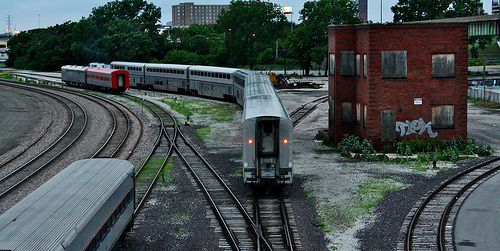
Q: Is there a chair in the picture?
A: No, there are no chairs.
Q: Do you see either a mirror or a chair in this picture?
A: No, there are no chairs or mirrors.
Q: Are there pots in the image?
A: No, there are no pots.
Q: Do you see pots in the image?
A: No, there are no pots.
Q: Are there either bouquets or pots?
A: No, there are no pots or bouquets.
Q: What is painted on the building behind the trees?
A: The graffiti is painted on the building.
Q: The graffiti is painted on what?
A: The graffiti is painted on the building.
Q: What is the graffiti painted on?
A: The graffiti is painted on the building.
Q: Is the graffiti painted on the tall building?
A: Yes, the graffiti is painted on the building.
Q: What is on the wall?
A: The graffiti is on the wall.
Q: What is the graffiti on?
A: The graffiti is on the wall.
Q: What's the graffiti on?
A: The graffiti is on the wall.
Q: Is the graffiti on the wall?
A: Yes, the graffiti is on the wall.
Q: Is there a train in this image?
A: Yes, there is a train.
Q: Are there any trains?
A: Yes, there is a train.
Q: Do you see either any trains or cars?
A: Yes, there is a train.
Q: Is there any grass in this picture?
A: Yes, there is grass.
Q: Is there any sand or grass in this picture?
A: Yes, there is grass.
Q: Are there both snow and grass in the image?
A: No, there is grass but no snow.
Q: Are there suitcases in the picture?
A: No, there are no suitcases.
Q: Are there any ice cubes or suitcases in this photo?
A: No, there are no suitcases or ice cubes.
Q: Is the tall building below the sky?
A: Yes, the building is below the sky.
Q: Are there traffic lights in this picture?
A: No, there are no traffic lights.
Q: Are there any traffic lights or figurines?
A: No, there are no traffic lights or figurines.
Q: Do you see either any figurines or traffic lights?
A: No, there are no traffic lights or figurines.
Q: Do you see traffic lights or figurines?
A: No, there are no traffic lights or figurines.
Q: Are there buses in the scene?
A: No, there are no buses.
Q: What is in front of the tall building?
A: The trees are in front of the building.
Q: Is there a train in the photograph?
A: Yes, there is a train.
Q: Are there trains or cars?
A: Yes, there is a train.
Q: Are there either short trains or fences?
A: Yes, there is a short train.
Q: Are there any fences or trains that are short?
A: Yes, the train is short.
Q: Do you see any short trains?
A: Yes, there is a short train.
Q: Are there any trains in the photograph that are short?
A: Yes, there is a train that is short.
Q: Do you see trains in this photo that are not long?
A: Yes, there is a short train.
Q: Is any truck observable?
A: No, there are no trucks.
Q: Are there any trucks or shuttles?
A: No, there are no trucks or shuttles.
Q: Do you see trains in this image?
A: Yes, there is a train.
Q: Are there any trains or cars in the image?
A: Yes, there is a train.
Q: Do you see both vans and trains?
A: No, there is a train but no vans.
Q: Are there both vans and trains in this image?
A: No, there is a train but no vans.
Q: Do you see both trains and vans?
A: No, there is a train but no vans.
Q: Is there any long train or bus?
A: Yes, there is a long train.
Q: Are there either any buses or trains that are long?
A: Yes, the train is long.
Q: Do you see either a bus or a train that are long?
A: Yes, the train is long.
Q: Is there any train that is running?
A: Yes, there is a train that is running.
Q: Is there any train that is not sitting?
A: Yes, there is a train that is running.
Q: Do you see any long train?
A: Yes, there is a long train.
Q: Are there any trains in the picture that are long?
A: Yes, there is a train that is long.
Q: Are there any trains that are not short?
A: Yes, there is a long train.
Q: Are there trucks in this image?
A: No, there are no trucks.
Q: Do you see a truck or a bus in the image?
A: No, there are no trucks or buses.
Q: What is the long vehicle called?
A: The vehicle is a train.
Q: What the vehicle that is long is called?
A: The vehicle is a train.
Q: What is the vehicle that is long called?
A: The vehicle is a train.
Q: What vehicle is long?
A: The vehicle is a train.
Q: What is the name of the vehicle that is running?
A: The vehicle is a train.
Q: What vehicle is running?
A: The vehicle is a train.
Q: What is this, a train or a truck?
A: This is a train.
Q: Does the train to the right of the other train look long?
A: Yes, the train is long.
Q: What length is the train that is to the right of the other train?
A: The train is long.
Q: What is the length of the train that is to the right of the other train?
A: The train is long.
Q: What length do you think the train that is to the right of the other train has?
A: The train has long length.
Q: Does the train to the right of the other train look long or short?
A: The train is long.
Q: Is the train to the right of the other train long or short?
A: The train is long.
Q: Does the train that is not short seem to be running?
A: Yes, the train is running.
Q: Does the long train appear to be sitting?
A: No, the train is running.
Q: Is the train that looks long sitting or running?
A: The train is running.